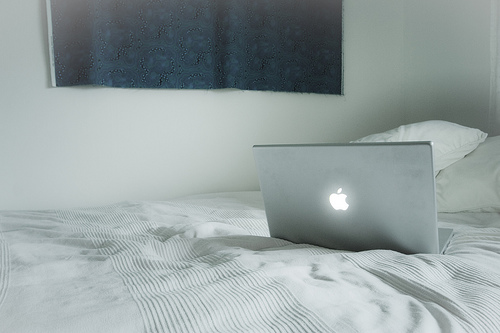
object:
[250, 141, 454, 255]
computer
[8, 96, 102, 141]
paint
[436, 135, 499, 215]
pillow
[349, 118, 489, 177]
pillow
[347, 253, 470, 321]
shadow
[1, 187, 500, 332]
bedspread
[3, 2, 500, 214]
walls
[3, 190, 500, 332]
blanket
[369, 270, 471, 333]
fold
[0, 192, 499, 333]
bed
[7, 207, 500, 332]
white comforter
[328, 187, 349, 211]
logo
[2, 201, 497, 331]
bedding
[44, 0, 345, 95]
window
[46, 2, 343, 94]
fabric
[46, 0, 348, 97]
panel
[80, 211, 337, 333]
lines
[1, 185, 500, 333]
spread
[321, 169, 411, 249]
shadow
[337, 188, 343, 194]
logo stem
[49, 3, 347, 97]
curtain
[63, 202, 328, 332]
ridged lines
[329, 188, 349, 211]
apple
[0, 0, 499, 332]
bedroom